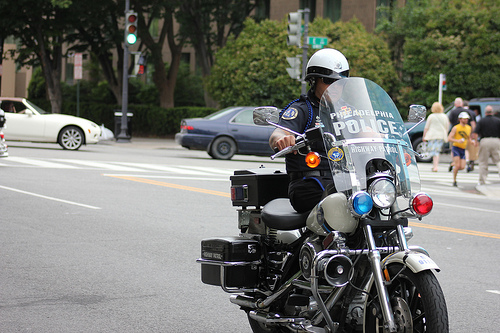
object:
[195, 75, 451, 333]
motorcycle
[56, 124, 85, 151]
tire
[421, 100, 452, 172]
person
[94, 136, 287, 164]
sidewalk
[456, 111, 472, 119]
hat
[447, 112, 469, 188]
person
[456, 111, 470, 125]
head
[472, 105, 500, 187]
person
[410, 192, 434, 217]
light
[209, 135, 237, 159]
tire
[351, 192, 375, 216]
blue light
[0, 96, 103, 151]
car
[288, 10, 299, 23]
signal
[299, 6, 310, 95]
pole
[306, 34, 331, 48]
street sign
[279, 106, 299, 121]
patch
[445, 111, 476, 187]
person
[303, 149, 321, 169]
light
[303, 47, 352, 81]
helmet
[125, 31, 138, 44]
light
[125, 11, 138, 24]
signal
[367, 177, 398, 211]
light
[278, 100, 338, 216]
uniform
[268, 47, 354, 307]
man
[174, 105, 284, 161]
car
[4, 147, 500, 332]
road